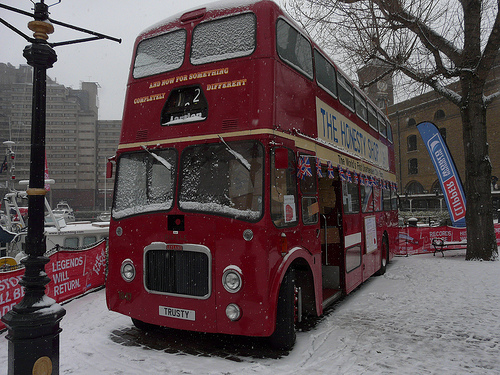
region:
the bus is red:
[104, 0, 401, 357]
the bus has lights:
[104, 249, 249, 329]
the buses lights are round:
[115, 245, 247, 329]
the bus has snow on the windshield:
[103, 133, 263, 222]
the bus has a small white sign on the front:
[154, 301, 200, 329]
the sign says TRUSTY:
[151, 299, 200, 328]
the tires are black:
[114, 257, 306, 373]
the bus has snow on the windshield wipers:
[131, 143, 255, 187]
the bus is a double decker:
[101, 0, 394, 364]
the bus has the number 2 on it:
[188, 82, 205, 110]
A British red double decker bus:
[102, 9, 379, 357]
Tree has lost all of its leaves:
[300, 1, 495, 265]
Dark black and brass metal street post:
[5, 5, 65, 370]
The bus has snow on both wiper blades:
[135, 135, 256, 170]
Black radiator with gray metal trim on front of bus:
[140, 240, 211, 296]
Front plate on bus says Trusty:
[151, 297, 201, 322]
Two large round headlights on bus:
[115, 252, 256, 297]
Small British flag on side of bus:
[295, 150, 310, 180]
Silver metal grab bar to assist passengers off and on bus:
[320, 210, 335, 295]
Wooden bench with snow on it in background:
[428, 232, 464, 255]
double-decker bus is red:
[91, 2, 412, 358]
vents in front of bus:
[130, 235, 217, 311]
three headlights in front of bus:
[103, 248, 255, 330]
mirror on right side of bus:
[265, 132, 295, 174]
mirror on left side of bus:
[93, 146, 120, 182]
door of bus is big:
[301, 156, 358, 313]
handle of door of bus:
[313, 205, 335, 277]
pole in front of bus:
[16, 0, 60, 373]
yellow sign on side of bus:
[306, 94, 400, 188]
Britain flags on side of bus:
[288, 144, 405, 200]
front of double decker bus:
[113, 227, 257, 327]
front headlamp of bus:
[222, 252, 257, 298]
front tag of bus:
[158, 282, 197, 349]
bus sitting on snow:
[331, 280, 423, 365]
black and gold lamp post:
[24, 27, 61, 270]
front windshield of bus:
[106, 136, 297, 242]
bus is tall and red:
[104, 130, 286, 348]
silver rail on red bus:
[313, 177, 338, 310]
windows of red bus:
[345, 173, 411, 231]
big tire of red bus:
[275, 261, 341, 350]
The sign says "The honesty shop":
[317, 104, 392, 169]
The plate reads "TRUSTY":
[158, 302, 198, 325]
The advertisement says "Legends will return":
[48, 254, 90, 295]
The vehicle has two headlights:
[117, 255, 242, 295]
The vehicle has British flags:
[295, 156, 395, 188]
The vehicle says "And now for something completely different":
[133, 64, 249, 104]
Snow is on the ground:
[342, 257, 494, 368]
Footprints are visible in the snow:
[328, 305, 491, 350]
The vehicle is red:
[112, 3, 399, 336]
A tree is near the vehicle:
[443, 4, 497, 261]